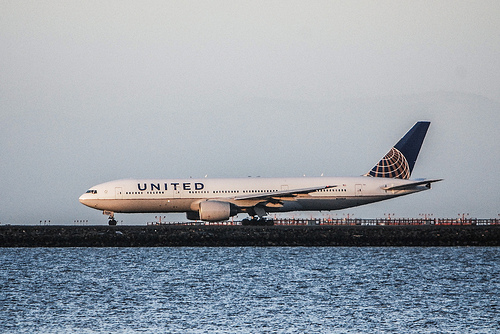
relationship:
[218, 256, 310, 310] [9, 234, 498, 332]
wave in water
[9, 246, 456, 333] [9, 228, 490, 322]
airplane above water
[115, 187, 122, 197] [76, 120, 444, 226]
door on airplane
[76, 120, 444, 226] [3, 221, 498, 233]
airplane on runway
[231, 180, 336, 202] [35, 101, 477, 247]
wing on airplane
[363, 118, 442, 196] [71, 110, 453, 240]
tail on plane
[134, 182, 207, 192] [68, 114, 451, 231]
writing on airplane